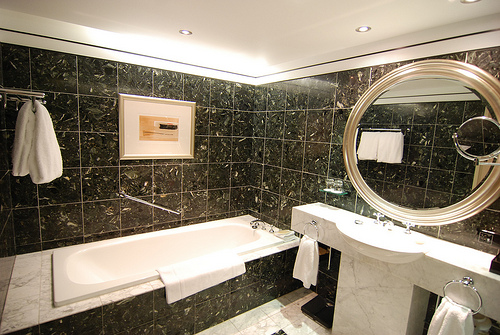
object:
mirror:
[341, 59, 497, 228]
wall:
[2, 39, 499, 259]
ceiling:
[0, 1, 499, 87]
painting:
[116, 92, 198, 161]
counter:
[290, 201, 499, 334]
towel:
[291, 235, 320, 289]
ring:
[301, 221, 321, 242]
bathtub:
[50, 213, 300, 306]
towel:
[11, 101, 63, 185]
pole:
[0, 88, 48, 113]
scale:
[299, 292, 335, 329]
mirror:
[451, 115, 499, 166]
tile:
[180, 164, 209, 192]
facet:
[379, 218, 397, 235]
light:
[353, 25, 373, 34]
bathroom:
[0, 1, 499, 332]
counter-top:
[289, 202, 499, 282]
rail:
[117, 189, 182, 216]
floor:
[195, 288, 339, 335]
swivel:
[472, 155, 500, 167]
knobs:
[372, 211, 412, 234]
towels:
[355, 129, 405, 165]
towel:
[155, 246, 247, 305]